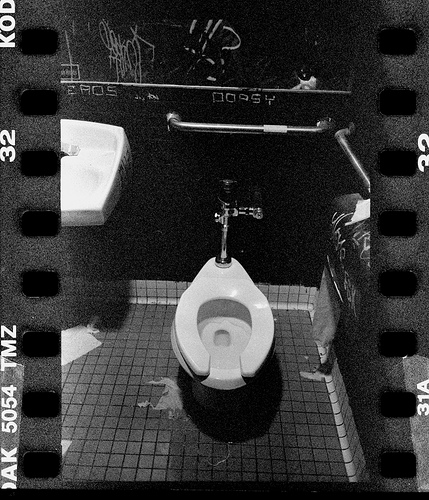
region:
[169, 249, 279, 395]
a toilet in a bathroom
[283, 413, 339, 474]
part of tile floor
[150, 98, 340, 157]
a chrome towel bar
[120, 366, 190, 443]
wet paper on the floor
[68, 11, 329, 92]
graffite on the wall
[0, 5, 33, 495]
letters and numbers on the image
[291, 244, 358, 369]
paper hanging from the wall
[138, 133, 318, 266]
a dark wall behind toilet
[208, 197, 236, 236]
a flush lever on toilet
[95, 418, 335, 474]
The floor is made of tile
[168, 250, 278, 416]
The toilet is the color white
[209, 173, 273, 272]
The pipe to the toilet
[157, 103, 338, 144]
The holding bar on the wall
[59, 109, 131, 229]
The sink is on the wall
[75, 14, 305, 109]
The wall has graffiti on it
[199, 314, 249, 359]
The water in the toilet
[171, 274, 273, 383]
The top of the toilet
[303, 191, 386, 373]
The toilet paper dispenser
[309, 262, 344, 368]
The toilet paper is the color white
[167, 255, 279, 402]
the toilet is color white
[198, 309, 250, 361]
water of toilet is clean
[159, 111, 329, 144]
the handle color silver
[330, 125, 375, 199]
the handle color silver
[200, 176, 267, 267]
a pipe over the toilet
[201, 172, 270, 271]
pipe is color silver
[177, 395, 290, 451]
shadow on the ground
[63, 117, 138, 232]
a sink color white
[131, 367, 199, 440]
white paper on floor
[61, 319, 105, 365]
white paper on the floor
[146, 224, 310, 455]
This is a toilet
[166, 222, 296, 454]
This is a toilet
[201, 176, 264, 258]
Silver piping connected to toilet.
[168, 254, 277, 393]
White porcelean toilet bowl.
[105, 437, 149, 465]
Small square tile floor.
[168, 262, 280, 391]
Empty clear toilet bowl.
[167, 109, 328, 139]
Silver handicapped handle bars.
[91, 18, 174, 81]
Graffiti on stall wall.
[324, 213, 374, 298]
Grafitti on side wall.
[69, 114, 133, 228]
Graffiti on side of sink.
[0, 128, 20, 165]
Photo number on side says 32.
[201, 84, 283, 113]
Where is the letter D?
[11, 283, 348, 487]
The tiled floor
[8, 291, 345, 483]
A tiled floor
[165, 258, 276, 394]
A white toilet